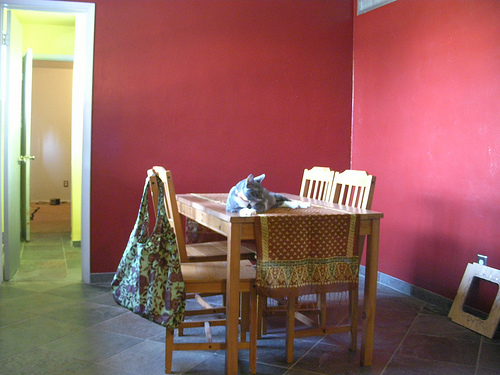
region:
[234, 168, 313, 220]
A gray cat on a wood table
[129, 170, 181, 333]
A bag draped over a chair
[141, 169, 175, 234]
The strap of the bag on the chair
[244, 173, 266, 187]
The cats ears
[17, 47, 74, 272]
The doorway at the end of the hall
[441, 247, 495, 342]
A piece of wood on the floor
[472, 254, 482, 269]
The outlet behind the piece of wood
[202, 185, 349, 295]
The runner on the table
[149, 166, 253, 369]
Wooden chairs around a table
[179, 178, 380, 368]
A wooden table with a cat on it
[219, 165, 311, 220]
gray cat on the table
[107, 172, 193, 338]
green and pink floral bag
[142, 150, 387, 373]
light brown wooden chairs and table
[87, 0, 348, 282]
red painted dining room wall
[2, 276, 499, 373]
grey tiled dining room floor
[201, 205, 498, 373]
shadows cast by table and chairs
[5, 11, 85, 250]
painted yellow wall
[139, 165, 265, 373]
light brown wooden chair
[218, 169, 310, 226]
grey cat with white feet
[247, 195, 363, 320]
brown, yellow, and green table cloth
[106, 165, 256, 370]
floral bag hanging on a wooden chair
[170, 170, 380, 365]
cat sitting on a dining room table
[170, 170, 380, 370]
cat resting on a table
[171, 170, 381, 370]
cat on top of a dining room table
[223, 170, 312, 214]
gray cat with a collar around its neck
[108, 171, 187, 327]
green and brown floral bag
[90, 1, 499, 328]
two red painted walls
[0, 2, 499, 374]
cat in a dining room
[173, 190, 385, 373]
wooden table with a cloth hanging off of it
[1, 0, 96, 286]
white frame of door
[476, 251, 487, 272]
an outlet in a wall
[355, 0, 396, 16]
a vent near the top of a wall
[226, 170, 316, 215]
a grey and white cat on a table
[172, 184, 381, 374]
a wooden dining room table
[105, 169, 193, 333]
a floral bag hanging on a chair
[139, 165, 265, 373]
a wooden chair at a dining room table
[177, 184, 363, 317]
a runner on the top of a table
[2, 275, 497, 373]
a tile dining room floor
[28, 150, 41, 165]
a doorknob on a door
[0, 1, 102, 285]
a white framed doorway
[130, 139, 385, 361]
dining room table in the room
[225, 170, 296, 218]
cat on the table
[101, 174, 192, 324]
bag on the chair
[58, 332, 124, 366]
tile on the floor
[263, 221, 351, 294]
runner on the table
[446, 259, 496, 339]
frame against the wall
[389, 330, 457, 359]
tile on the floor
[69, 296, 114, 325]
tile on the floor